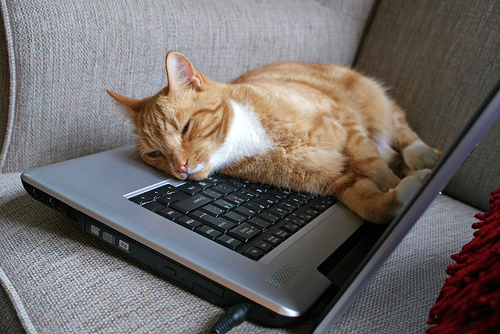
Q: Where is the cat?
A: On the laptop.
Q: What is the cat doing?
A: Sleeping.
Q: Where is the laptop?
A: On the couch.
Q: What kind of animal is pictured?
A: A cat.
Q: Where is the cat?
A: Lying on the computer.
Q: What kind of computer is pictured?
A: A laptop.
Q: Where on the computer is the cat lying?
A: On the keyboard.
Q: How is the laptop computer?
A: With the top open.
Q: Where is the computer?
A: On a chair.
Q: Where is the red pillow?
A: On the sofa chair.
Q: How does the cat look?
A: Sleepy.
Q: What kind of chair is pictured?
A: A grey sofa chair.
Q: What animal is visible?
A: A cat.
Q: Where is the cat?
A: On the laptop.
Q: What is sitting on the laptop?
A: A cat.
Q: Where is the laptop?
A: On a chair.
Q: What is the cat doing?
A: Lying down.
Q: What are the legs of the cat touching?
A: The screen.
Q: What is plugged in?
A: The laptop.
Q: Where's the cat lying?
A: On laptop.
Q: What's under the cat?
A: Laptop.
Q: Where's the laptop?
A: On the chair.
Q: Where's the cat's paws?
A: On the screen.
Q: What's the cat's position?
A: Lying down.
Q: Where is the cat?
A: On the laptop.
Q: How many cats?
A: One.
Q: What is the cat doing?
A: Laying down.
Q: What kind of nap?
A: Cat nap.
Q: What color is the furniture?
A: Gray.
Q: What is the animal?
A: A cat.